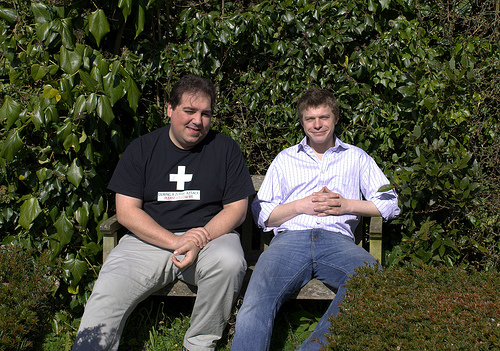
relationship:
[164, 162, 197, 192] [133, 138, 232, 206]
cross on shirt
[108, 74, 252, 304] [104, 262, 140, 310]
man wearing jeans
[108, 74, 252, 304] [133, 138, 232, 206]
man wearing shirt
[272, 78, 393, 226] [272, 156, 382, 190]
man wearing shirt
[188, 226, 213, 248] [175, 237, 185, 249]
hand on wrist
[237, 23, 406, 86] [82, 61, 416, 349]
trees are surrounding men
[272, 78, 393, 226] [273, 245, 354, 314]
man wearing jeans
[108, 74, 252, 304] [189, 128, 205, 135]
man wearing a smile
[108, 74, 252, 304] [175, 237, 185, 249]
man holding wrist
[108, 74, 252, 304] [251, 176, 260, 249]
man on bench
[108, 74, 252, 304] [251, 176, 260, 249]
man sitting on bench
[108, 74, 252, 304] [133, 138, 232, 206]
man wearing a shirt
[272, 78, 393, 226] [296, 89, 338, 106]
man has light hair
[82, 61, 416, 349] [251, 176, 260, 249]
men sitting on bench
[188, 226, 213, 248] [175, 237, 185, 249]
hand holding wrist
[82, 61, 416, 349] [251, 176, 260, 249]
men are sitting on bench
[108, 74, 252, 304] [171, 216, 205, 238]
man with hands on belly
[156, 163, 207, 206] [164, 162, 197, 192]
logo of a cross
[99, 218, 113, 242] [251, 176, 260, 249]
arm on bench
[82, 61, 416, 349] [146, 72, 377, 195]
men siting next to each other